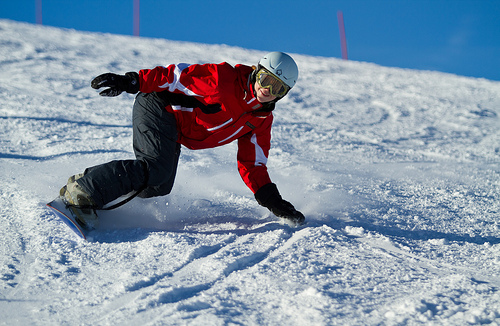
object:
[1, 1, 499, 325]
photo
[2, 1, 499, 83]
sky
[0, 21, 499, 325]
snow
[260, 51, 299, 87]
helmet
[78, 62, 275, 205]
jacket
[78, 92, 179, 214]
trouser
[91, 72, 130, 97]
glove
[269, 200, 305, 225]
glove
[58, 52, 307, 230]
woman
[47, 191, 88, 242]
snowboard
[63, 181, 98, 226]
feet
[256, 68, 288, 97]
goggles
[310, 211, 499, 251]
shadow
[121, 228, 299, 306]
tracks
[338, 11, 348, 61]
pole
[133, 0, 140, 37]
pole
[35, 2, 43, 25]
pole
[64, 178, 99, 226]
shoes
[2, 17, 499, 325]
ground